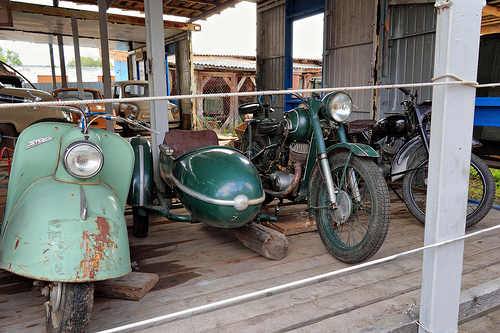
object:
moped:
[0, 83, 160, 332]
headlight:
[64, 141, 105, 179]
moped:
[231, 77, 392, 263]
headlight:
[329, 91, 352, 122]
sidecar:
[129, 130, 265, 238]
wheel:
[41, 279, 99, 332]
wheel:
[313, 151, 390, 264]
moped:
[342, 87, 496, 230]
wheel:
[400, 152, 496, 230]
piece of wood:
[96, 272, 159, 301]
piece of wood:
[226, 223, 289, 261]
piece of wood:
[265, 218, 319, 235]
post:
[421, 0, 487, 331]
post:
[143, 0, 168, 193]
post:
[98, 0, 117, 130]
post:
[70, 20, 87, 111]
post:
[56, 33, 67, 89]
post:
[49, 43, 58, 93]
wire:
[0, 80, 497, 110]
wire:
[93, 222, 499, 332]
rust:
[75, 215, 116, 279]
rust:
[14, 238, 21, 249]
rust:
[8, 262, 12, 271]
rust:
[283, 165, 302, 197]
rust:
[359, 153, 379, 159]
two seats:
[162, 123, 291, 159]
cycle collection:
[0, 88, 496, 331]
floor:
[1, 180, 497, 332]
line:
[276, 283, 423, 332]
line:
[158, 254, 259, 280]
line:
[137, 239, 239, 261]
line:
[462, 259, 500, 277]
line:
[373, 245, 430, 265]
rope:
[414, 321, 432, 333]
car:
[52, 87, 117, 131]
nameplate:
[26, 135, 56, 150]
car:
[111, 80, 180, 131]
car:
[0, 85, 71, 148]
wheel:
[129, 137, 152, 238]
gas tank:
[266, 171, 294, 192]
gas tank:
[377, 163, 391, 178]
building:
[327, 0, 438, 121]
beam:
[340, 48, 347, 90]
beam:
[351, 46, 359, 86]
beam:
[336, 3, 341, 45]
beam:
[360, 0, 367, 40]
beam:
[323, 52, 332, 87]